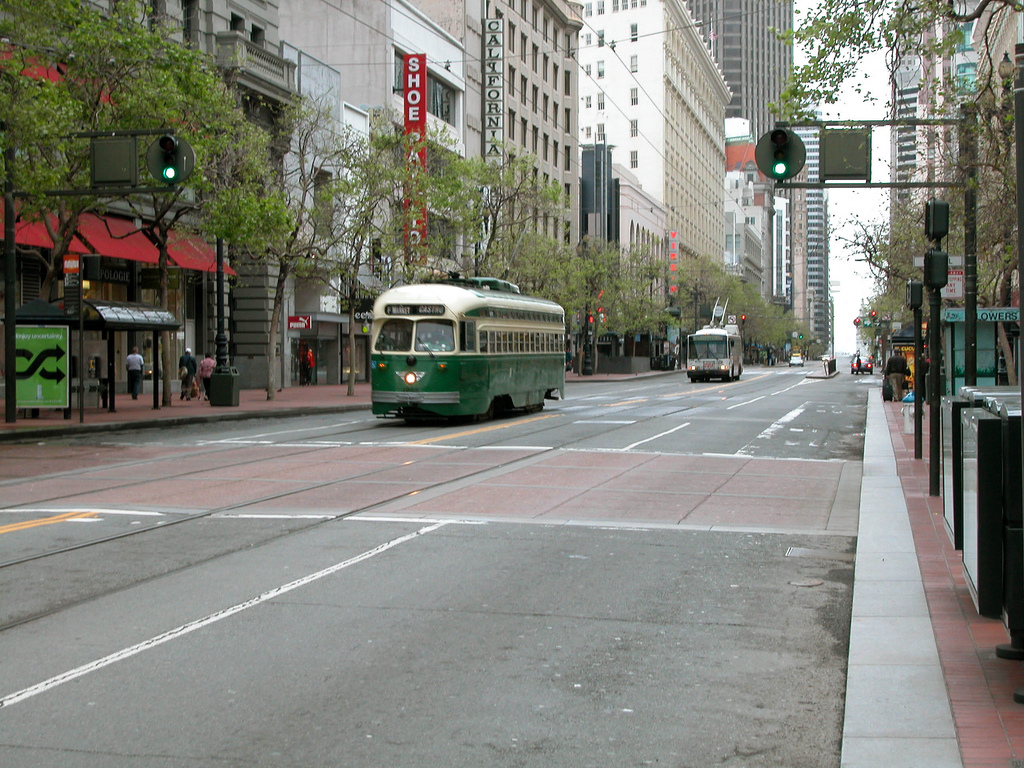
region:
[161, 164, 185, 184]
Green light illuminated on traffic signal.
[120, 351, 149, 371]
Person wearing white shirt.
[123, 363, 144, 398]
Person wearing black pants.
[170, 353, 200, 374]
Person wearing dark shirt.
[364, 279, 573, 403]
Green and white bus driving on road.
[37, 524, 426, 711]
White line marking pavement.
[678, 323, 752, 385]
Large bus driving on road.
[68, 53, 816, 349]
Buildings line the street.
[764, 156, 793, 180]
the street light is green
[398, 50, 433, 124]
the sign is red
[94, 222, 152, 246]
the awning is red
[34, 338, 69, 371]
the arrow is black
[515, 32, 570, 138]
the building has a lot of windows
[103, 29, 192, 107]
the tree has green leaves on it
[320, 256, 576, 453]
green and yellow bus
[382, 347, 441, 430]
white light on bus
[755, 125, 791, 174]
traffic light is green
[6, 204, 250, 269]
red awning on building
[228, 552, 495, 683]
road is light grey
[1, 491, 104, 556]
yellow line on road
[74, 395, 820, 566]
crosswalk is red brick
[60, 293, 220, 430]
black canopy over bus stop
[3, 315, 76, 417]
green and black sign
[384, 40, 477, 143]
windows on a building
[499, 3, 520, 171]
windows on a building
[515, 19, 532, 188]
windows on a building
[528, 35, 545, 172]
windows on a building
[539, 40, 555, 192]
windows on a building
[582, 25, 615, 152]
windows on a building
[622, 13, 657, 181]
windows on a building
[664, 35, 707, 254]
windows on a building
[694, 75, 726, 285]
windows on a building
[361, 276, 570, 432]
green and white bus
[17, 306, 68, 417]
green sign with black arrows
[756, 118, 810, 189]
lit green traffic light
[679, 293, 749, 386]
white bus driving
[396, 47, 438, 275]
red business sign with white lettering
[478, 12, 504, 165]
white business sign with black lettering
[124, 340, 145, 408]
man wearing white shirt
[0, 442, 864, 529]
red brick crosswalk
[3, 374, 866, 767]
grey street with white lines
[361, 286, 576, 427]
bus with orange headlights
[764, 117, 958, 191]
a street light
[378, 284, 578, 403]
a green street car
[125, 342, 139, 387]
a person in a white shirt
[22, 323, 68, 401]
a green sign on the sidewalk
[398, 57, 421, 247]
a red sign on the building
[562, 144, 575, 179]
A window on a building.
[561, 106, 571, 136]
A window on a building.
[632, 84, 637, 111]
A window on a building.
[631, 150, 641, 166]
A window on a building.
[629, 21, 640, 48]
A window on a building.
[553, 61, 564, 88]
A window on a building.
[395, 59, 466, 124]
A window on a building.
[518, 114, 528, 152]
A window on a building.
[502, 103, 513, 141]
A window on a building.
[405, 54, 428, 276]
the sign is red and white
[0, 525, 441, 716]
white painted line on the road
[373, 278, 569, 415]
white and green bus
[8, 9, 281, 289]
a tree with green leaves